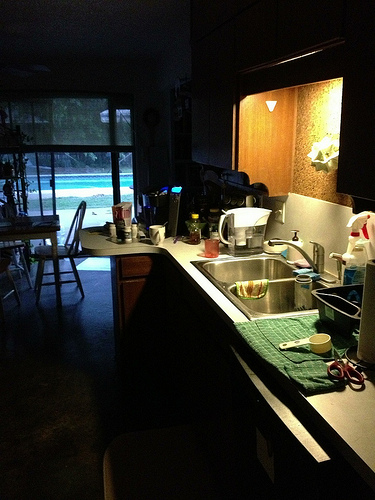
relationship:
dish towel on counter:
[234, 315, 355, 395] [81, 218, 372, 472]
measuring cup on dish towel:
[279, 335, 330, 354] [234, 315, 355, 395]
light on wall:
[307, 136, 339, 170] [291, 76, 348, 271]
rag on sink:
[237, 281, 269, 300] [193, 259, 324, 318]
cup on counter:
[148, 225, 167, 244] [81, 218, 372, 472]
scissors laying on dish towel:
[330, 346, 363, 386] [234, 315, 355, 395]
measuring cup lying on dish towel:
[279, 335, 330, 354] [234, 315, 355, 395]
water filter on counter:
[219, 15, 347, 207] [81, 218, 372, 472]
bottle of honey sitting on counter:
[190, 213, 201, 243] [81, 218, 372, 472]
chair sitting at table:
[34, 202, 87, 304] [0, 216, 66, 318]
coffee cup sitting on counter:
[148, 225, 167, 244] [81, 218, 372, 472]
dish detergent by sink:
[343, 255, 358, 285] [193, 259, 324, 318]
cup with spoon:
[148, 225, 167, 244] [160, 222, 167, 227]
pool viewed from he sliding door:
[1, 173, 127, 199] [16, 95, 121, 234]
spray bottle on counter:
[344, 211, 371, 270] [81, 218, 372, 472]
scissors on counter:
[330, 346, 363, 386] [81, 218, 372, 472]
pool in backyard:
[1, 173, 127, 199] [12, 96, 137, 231]